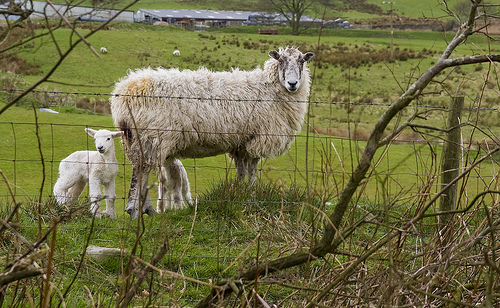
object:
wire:
[0, 89, 500, 110]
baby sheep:
[53, 128, 123, 218]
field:
[0, 3, 498, 308]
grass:
[0, 0, 500, 308]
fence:
[0, 88, 500, 308]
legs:
[124, 137, 171, 207]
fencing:
[0, 89, 500, 308]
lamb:
[157, 158, 197, 214]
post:
[437, 93, 463, 246]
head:
[269, 48, 315, 93]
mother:
[109, 48, 313, 219]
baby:
[53, 127, 125, 218]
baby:
[157, 158, 194, 214]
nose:
[287, 80, 298, 88]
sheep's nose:
[98, 145, 103, 148]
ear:
[112, 131, 124, 138]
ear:
[85, 128, 97, 137]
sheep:
[100, 47, 107, 53]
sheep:
[173, 50, 180, 56]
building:
[0, 0, 354, 30]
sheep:
[109, 48, 315, 221]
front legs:
[232, 137, 292, 184]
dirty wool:
[122, 77, 156, 108]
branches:
[0, 0, 500, 308]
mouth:
[288, 85, 298, 91]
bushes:
[404, 62, 500, 126]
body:
[113, 70, 310, 155]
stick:
[441, 96, 465, 234]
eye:
[278, 59, 282, 65]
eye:
[300, 59, 306, 64]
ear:
[300, 52, 315, 63]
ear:
[268, 50, 284, 62]